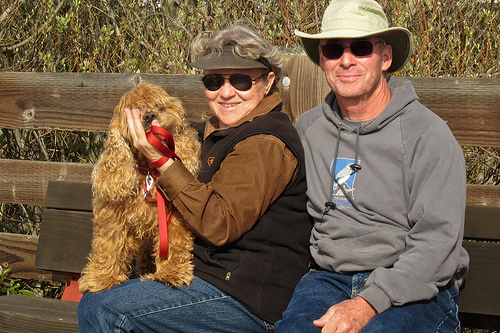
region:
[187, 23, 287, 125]
The woman is wearing sunglasses.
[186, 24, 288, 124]
The woman has gray hair.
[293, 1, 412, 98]
The man is wearing a hat.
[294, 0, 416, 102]
The man is wearing sunglasses.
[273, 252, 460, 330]
The man is wearing blue jeans.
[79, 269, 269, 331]
The woman is wearing blue jeans.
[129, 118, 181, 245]
woman holding a red leech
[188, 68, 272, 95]
woman wearing sunglasses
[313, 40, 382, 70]
man wearing sunglasses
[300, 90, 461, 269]
man wearing a gray shirt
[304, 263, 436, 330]
man wearing blue jeans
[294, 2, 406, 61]
man wearing a brown hat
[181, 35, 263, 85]
woman wearing brown hat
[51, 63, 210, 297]
dog on the bench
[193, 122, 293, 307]
woman wearing a black vest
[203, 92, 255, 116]
woman with a smile on her face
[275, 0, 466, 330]
Man sitting on bench with woman and dog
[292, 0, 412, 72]
Beige hat on man sitting on bench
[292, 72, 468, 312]
Gray sweatshirt on man sitting on bench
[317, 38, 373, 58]
Sunglasses on man sitting on bench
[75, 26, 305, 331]
Woman on bench with man and a dog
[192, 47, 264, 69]
Brown visor on woman sitting on bench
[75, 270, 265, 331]
Blue jeans on woman sitting on bench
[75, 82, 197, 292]
Golden dog on bench with man and woman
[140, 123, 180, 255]
Red leash of gold colored dog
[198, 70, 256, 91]
Sunglasses on woman sitting on bench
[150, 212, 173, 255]
lesh on the dog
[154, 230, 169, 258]
the leash is red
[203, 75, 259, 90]
women wearing sun glasses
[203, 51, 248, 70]
a visor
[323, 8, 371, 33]
man wearing a hat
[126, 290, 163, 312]
jeans are blue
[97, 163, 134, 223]
the dog is brown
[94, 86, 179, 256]
A brown dog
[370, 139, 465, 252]
A gray hoodie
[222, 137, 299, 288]
A brown and black sweater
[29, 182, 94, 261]
A wooden bench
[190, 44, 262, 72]
A brown hat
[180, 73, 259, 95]
Glasses on the eyes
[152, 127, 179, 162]
A red ribbon in the hands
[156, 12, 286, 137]
head of the person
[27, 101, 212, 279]
brown dog next to people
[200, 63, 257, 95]
the shades are dark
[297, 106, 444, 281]
the sweatshirt is gray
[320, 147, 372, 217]
the design is on sweatshirt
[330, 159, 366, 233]
the design is blue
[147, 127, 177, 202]
the leash is red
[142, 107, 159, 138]
the nose is black